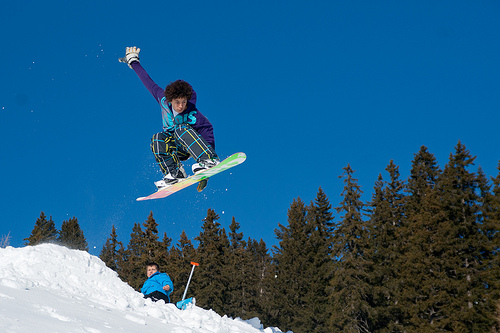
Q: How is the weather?
A: It is clear.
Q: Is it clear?
A: Yes, it is clear.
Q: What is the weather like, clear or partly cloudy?
A: It is clear.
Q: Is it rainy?
A: No, it is clear.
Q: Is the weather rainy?
A: No, it is clear.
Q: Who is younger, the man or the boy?
A: The boy is younger than the man.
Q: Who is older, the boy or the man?
A: The man is older than the boy.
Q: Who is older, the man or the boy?
A: The man is older than the boy.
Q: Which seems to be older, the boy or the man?
A: The man is older than the boy.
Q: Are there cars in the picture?
A: No, there are no cars.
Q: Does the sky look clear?
A: Yes, the sky is clear.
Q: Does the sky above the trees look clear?
A: Yes, the sky is clear.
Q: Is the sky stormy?
A: No, the sky is clear.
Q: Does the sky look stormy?
A: No, the sky is clear.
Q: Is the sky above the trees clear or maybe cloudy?
A: The sky is clear.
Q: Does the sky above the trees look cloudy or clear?
A: The sky is clear.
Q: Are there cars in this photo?
A: No, there are no cars.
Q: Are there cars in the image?
A: No, there are no cars.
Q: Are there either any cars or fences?
A: No, there are no cars or fences.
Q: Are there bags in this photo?
A: No, there are no bags.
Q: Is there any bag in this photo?
A: No, there are no bags.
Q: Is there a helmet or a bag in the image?
A: No, there are no bags or helmets.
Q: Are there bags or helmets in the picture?
A: No, there are no bags or helmets.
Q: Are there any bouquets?
A: No, there are no bouquets.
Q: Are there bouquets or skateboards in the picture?
A: No, there are no bouquets or skateboards.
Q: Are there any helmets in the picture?
A: No, there are no helmets.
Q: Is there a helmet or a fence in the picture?
A: No, there are no helmets or fences.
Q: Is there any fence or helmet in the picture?
A: No, there are no helmets or fences.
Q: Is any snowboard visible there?
A: Yes, there is a snowboard.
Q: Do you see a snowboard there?
A: Yes, there is a snowboard.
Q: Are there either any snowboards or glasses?
A: Yes, there is a snowboard.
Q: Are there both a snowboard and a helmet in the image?
A: No, there is a snowboard but no helmets.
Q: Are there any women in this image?
A: No, there are no women.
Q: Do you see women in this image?
A: No, there are no women.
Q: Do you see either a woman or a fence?
A: No, there are no women or fences.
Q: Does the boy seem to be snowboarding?
A: Yes, the boy is snowboarding.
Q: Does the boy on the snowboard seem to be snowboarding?
A: Yes, the boy is snowboarding.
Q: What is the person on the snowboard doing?
A: The boy is snowboarding.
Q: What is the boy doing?
A: The boy is snowboarding.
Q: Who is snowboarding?
A: The boy is snowboarding.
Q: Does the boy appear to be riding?
A: No, the boy is snowboarding.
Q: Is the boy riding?
A: No, the boy is snowboarding.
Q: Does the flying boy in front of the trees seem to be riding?
A: No, the boy is snowboarding.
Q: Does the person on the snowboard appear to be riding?
A: No, the boy is snowboarding.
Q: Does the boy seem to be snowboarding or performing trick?
A: The boy is snowboarding.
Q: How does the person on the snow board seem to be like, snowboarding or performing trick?
A: The boy is snowboarding.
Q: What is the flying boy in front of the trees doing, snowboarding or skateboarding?
A: The boy is snowboarding.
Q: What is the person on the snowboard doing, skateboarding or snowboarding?
A: The boy is snowboarding.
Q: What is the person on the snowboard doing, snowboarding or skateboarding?
A: The boy is snowboarding.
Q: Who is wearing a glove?
A: The boy is wearing a glove.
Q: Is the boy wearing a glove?
A: Yes, the boy is wearing a glove.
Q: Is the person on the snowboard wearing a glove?
A: Yes, the boy is wearing a glove.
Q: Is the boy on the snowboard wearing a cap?
A: No, the boy is wearing a glove.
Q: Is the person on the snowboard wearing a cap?
A: No, the boy is wearing a glove.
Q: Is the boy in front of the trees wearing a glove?
A: Yes, the boy is wearing a glove.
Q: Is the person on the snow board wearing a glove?
A: Yes, the boy is wearing a glove.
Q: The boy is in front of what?
A: The boy is in front of the trees.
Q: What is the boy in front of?
A: The boy is in front of the trees.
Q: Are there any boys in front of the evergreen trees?
A: Yes, there is a boy in front of the trees.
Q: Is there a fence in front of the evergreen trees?
A: No, there is a boy in front of the trees.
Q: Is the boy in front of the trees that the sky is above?
A: Yes, the boy is in front of the trees.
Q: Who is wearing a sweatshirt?
A: The boy is wearing a sweatshirt.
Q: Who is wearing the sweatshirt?
A: The boy is wearing a sweatshirt.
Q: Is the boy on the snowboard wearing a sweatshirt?
A: Yes, the boy is wearing a sweatshirt.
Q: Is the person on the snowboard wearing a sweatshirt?
A: Yes, the boy is wearing a sweatshirt.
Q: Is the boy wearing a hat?
A: No, the boy is wearing a sweatshirt.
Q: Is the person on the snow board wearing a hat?
A: No, the boy is wearing a sweatshirt.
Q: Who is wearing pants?
A: The boy is wearing pants.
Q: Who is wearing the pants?
A: The boy is wearing pants.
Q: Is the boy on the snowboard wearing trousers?
A: Yes, the boy is wearing trousers.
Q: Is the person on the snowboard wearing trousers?
A: Yes, the boy is wearing trousers.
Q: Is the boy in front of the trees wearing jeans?
A: No, the boy is wearing trousers.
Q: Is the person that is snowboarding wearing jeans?
A: No, the boy is wearing trousers.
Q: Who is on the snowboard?
A: The boy is on the snowboard.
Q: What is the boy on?
A: The boy is on the snow board.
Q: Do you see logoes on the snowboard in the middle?
A: No, there is a boy on the snow board.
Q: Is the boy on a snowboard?
A: Yes, the boy is on a snowboard.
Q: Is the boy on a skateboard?
A: No, the boy is on a snowboard.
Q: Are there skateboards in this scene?
A: No, there are no skateboards.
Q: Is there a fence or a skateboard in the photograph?
A: No, there are no skateboards or fences.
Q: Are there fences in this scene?
A: No, there are no fences.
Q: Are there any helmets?
A: No, there are no helmets.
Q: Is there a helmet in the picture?
A: No, there are no helmets.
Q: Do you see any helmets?
A: No, there are no helmets.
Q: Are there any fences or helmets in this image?
A: No, there are no helmets or fences.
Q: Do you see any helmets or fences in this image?
A: No, there are no helmets or fences.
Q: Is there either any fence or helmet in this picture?
A: No, there are no helmets or fences.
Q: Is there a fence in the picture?
A: No, there are no fences.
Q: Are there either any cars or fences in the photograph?
A: No, there are no fences or cars.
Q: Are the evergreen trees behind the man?
A: Yes, the trees are behind the man.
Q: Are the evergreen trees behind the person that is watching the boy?
A: Yes, the trees are behind the man.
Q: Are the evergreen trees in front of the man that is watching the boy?
A: No, the trees are behind the man.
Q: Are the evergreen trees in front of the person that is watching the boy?
A: No, the trees are behind the man.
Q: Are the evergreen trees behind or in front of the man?
A: The trees are behind the man.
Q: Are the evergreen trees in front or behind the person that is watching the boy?
A: The trees are behind the man.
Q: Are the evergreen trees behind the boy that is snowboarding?
A: Yes, the trees are behind the boy.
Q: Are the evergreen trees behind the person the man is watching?
A: Yes, the trees are behind the boy.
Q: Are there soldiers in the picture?
A: No, there are no soldiers.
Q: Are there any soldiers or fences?
A: No, there are no soldiers or fences.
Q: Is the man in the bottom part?
A: Yes, the man is in the bottom of the image.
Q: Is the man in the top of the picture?
A: No, the man is in the bottom of the image.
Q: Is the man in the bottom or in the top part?
A: The man is in the bottom of the image.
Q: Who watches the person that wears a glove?
A: The man watches the boy.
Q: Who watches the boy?
A: The man watches the boy.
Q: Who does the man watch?
A: The man watches the boy.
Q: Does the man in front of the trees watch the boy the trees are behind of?
A: Yes, the man watches the boy.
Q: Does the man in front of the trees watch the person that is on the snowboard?
A: Yes, the man watches the boy.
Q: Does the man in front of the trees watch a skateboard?
A: No, the man watches the boy.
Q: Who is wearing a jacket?
A: The man is wearing a jacket.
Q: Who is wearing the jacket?
A: The man is wearing a jacket.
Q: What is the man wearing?
A: The man is wearing a jacket.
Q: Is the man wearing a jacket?
A: Yes, the man is wearing a jacket.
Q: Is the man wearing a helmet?
A: No, the man is wearing a jacket.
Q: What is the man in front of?
A: The man is in front of the trees.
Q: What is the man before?
A: The man is in front of the trees.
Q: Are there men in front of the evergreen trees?
A: Yes, there is a man in front of the trees.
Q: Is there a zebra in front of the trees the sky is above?
A: No, there is a man in front of the trees.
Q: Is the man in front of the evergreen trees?
A: Yes, the man is in front of the trees.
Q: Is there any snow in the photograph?
A: Yes, there is snow.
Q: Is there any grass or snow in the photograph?
A: Yes, there is snow.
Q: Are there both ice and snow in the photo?
A: No, there is snow but no ice.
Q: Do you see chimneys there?
A: No, there are no chimneys.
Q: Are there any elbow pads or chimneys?
A: No, there are no chimneys or elbow pads.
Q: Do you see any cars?
A: No, there are no cars.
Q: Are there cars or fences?
A: No, there are no cars or fences.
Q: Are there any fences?
A: No, there are no fences.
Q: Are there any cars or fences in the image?
A: No, there are no fences or cars.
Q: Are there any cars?
A: No, there are no cars.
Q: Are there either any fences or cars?
A: No, there are no cars or fences.